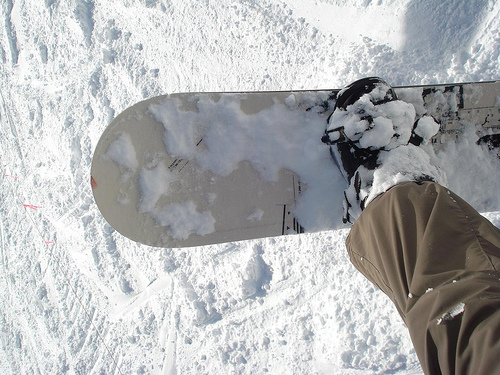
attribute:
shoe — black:
[321, 72, 439, 225]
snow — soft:
[1, 246, 343, 374]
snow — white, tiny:
[1, 3, 498, 374]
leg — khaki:
[328, 175, 498, 372]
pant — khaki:
[345, 180, 497, 374]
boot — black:
[325, 76, 420, 176]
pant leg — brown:
[344, 175, 499, 374]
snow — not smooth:
[6, 8, 498, 68]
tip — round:
[91, 90, 187, 248]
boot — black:
[329, 74, 439, 204]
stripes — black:
[282, 94, 471, 232]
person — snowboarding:
[324, 76, 495, 373]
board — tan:
[96, 96, 498, 242]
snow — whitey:
[112, 263, 226, 340]